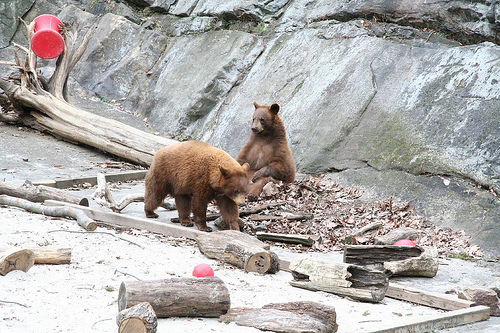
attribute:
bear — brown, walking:
[146, 138, 250, 233]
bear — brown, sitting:
[238, 103, 295, 199]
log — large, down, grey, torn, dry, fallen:
[0, 16, 184, 169]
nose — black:
[251, 125, 259, 132]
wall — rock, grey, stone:
[1, 1, 498, 257]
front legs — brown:
[194, 194, 241, 233]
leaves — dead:
[251, 176, 477, 260]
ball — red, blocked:
[192, 263, 215, 277]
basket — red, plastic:
[31, 15, 67, 60]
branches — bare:
[1, 15, 103, 122]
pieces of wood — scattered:
[116, 280, 338, 332]